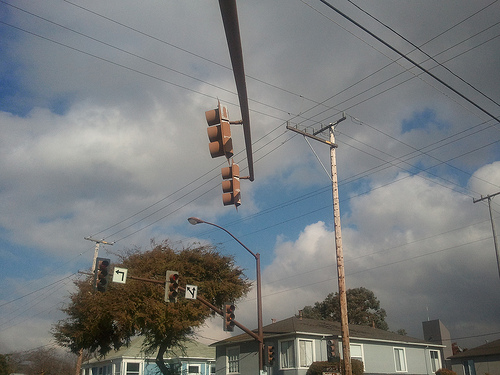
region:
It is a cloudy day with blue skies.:
[36, 73, 177, 213]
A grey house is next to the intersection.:
[356, 329, 433, 374]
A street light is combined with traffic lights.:
[183, 216, 292, 370]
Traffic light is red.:
[161, 262, 186, 310]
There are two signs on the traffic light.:
[113, 265, 219, 308]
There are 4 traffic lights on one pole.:
[94, 262, 282, 372]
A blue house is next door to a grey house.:
[111, 335, 231, 372]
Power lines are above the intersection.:
[104, 126, 178, 245]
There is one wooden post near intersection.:
[326, 149, 371, 369]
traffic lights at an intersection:
[60, 96, 341, 373]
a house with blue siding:
[213, 313, 443, 373]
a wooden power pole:
[283, 105, 364, 373]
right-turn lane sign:
[110, 265, 126, 285]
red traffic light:
[161, 270, 181, 306]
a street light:
[186, 207, 267, 368]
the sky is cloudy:
[1, 1, 494, 325]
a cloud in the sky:
[3, 80, 258, 271]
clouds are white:
[4, 2, 493, 354]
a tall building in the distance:
[422, 315, 454, 374]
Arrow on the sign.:
[111, 262, 128, 287]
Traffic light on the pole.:
[162, 265, 181, 303]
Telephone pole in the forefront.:
[324, 119, 355, 374]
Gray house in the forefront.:
[211, 313, 446, 374]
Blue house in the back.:
[78, 325, 217, 373]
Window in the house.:
[390, 345, 410, 372]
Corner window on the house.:
[275, 337, 318, 369]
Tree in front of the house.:
[52, 240, 254, 372]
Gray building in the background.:
[421, 315, 453, 362]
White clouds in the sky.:
[7, 8, 497, 372]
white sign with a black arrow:
[111, 267, 127, 282]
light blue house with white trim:
[81, 335, 215, 374]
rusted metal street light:
[204, 98, 233, 158]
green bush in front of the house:
[305, 356, 363, 373]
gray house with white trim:
[209, 315, 444, 372]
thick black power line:
[320, 0, 496, 122]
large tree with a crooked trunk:
[50, 238, 253, 370]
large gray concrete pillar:
[421, 318, 454, 369]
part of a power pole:
[83, 235, 115, 287]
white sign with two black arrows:
[183, 283, 197, 299]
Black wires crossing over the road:
[18, 2, 493, 275]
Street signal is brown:
[205, 104, 245, 209]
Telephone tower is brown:
[313, 111, 361, 371]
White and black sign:
[112, 268, 129, 286]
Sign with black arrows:
[183, 284, 200, 304]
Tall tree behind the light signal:
[70, 234, 237, 371]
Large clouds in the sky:
[39, 2, 491, 325]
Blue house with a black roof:
[215, 321, 439, 373]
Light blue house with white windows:
[84, 337, 218, 372]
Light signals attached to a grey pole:
[200, 7, 260, 212]